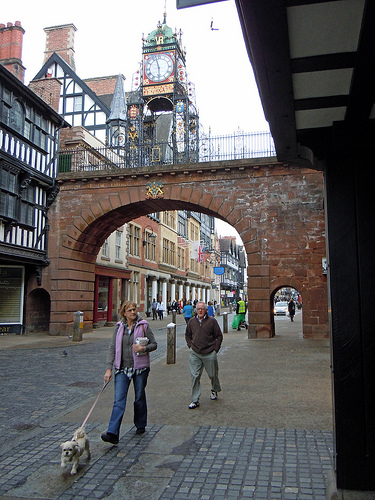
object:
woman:
[101, 299, 158, 442]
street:
[0, 346, 141, 474]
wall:
[248, 195, 323, 336]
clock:
[140, 49, 175, 95]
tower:
[126, 6, 202, 165]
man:
[185, 302, 224, 408]